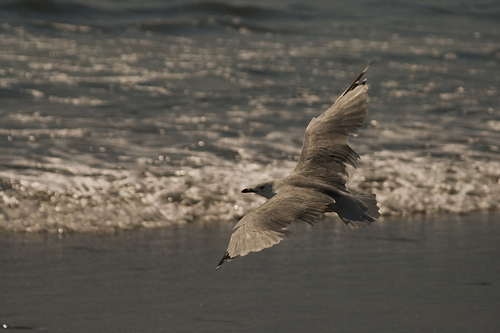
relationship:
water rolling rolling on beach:
[52, 152, 220, 244] [0, 207, 500, 331]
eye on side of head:
[255, 186, 263, 193] [238, 179, 275, 201]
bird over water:
[213, 57, 380, 269] [4, 200, 496, 333]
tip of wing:
[214, 250, 236, 268] [199, 191, 342, 287]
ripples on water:
[49, 143, 206, 211] [61, 67, 218, 160]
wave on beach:
[6, 139, 494, 257] [0, 207, 500, 331]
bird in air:
[213, 57, 380, 269] [5, 38, 496, 329]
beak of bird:
[229, 181, 260, 203] [192, 90, 399, 295]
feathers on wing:
[327, 86, 372, 198] [302, 68, 371, 180]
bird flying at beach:
[213, 57, 380, 269] [255, 257, 365, 302]